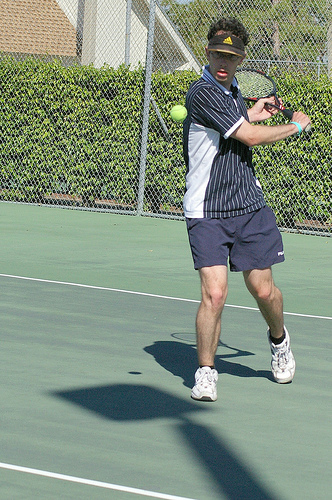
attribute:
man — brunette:
[177, 12, 312, 404]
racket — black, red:
[233, 66, 311, 133]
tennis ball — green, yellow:
[166, 103, 188, 127]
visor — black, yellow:
[204, 32, 248, 62]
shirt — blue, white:
[181, 64, 267, 220]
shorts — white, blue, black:
[183, 204, 286, 273]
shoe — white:
[189, 363, 221, 408]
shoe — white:
[265, 322, 297, 386]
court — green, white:
[1, 199, 329, 499]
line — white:
[1, 270, 331, 325]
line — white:
[1, 456, 203, 500]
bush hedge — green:
[1, 55, 331, 225]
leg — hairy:
[191, 226, 232, 384]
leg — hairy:
[234, 216, 287, 345]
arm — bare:
[193, 88, 309, 150]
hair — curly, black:
[205, 15, 251, 46]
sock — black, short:
[267, 328, 288, 345]